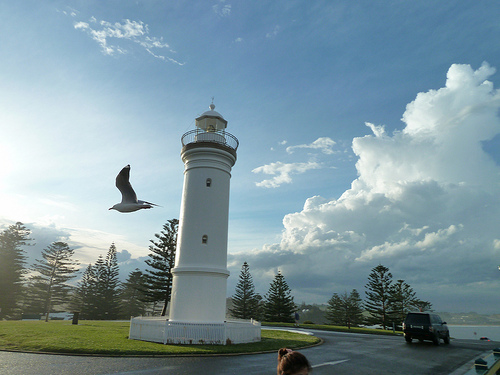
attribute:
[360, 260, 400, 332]
tree — vegetated, background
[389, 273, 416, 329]
tree — vegetated, background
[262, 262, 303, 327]
tree — vegetated, background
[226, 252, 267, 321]
tree — vegetated, background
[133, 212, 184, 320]
tree — vegetated, background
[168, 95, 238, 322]
lighthouse — white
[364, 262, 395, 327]
tree — large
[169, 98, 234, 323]
white monument — central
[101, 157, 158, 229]
bird — flying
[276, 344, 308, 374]
head — partially seen, human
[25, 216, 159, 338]
tree — large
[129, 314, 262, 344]
fence — white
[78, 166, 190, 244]
bird — flying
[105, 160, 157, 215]
bird — flying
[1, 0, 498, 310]
sky — blue, clouded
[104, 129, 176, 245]
bird — flying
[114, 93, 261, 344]
lighthouse — white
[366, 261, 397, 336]
tree — tall, green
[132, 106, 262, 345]
building — white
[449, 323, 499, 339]
lake — gray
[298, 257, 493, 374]
water — blue, body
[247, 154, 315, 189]
cloud — white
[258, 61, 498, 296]
cloud — white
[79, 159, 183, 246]
bird — white, flying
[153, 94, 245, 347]
lighthouse — tall, white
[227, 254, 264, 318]
tree — large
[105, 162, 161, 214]
bird — big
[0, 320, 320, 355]
grass — green, circle, large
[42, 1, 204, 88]
clouds — white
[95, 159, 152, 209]
seagull — flying in air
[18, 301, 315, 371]
green space — rounded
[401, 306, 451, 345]
suv — black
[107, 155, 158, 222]
bird — big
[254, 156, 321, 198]
cloud — White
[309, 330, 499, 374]
pavement — dark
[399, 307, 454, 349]
car — dark, parked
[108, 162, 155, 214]
bird — big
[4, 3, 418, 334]
day — bright